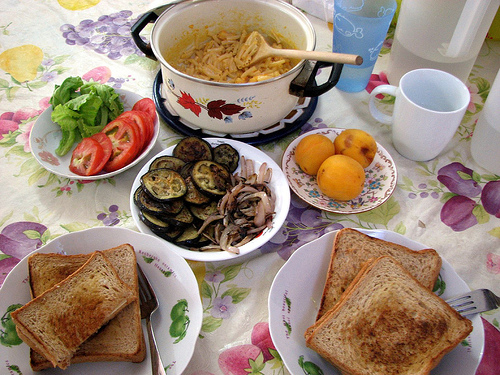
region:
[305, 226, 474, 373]
two slices of toast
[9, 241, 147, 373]
one and a half slices of toast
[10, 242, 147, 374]
a half slice of toast on top of a toast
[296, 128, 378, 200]
three orange and brown fruits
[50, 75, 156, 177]
slices of tomatoes and lettuce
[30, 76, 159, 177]
tomato slices and lettuce in a white and pink floral bowl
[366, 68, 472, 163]
a white coffee cup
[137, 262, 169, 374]
a sterling steel fork on the plate of toast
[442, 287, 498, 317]
a fork on the side of the plate and table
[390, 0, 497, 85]
water in a plastic transparent pitcher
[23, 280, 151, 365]
Square piece of toast on plate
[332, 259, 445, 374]
Square piece of toast on plate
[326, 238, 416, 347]
Square piece of toast on plate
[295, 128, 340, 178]
Orange sitting on plate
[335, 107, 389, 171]
Orange sitting on plate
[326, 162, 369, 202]
Orange sitting on plate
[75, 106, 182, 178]
sliced tomatos in bowl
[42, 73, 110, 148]
chopped lettuce in bowl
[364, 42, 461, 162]
empty white mug on table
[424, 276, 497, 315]
silver fork on bowl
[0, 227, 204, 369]
a white and green plate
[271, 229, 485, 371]
a white and green plate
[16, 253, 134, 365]
a piece of toast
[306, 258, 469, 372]
a piece of toast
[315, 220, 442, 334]
a piece of toast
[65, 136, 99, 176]
a slice of red tomato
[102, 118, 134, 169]
a slice of red tomato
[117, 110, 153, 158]
a slice of red tomato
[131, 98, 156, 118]
a slice of red tomato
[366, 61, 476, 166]
A white cup on a table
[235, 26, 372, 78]
A wooden spoon in a bowl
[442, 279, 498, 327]
A fork resting on a plate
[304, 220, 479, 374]
Two pieces of toast on a plate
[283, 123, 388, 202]
3 peices of fruit on a plate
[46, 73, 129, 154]
Some Lettuce on a white plate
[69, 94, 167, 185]
Tomatoes on a white plate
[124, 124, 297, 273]
Food in a white bowl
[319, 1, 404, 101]
An empty glass on a table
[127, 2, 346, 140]
A pot of noodles on a table